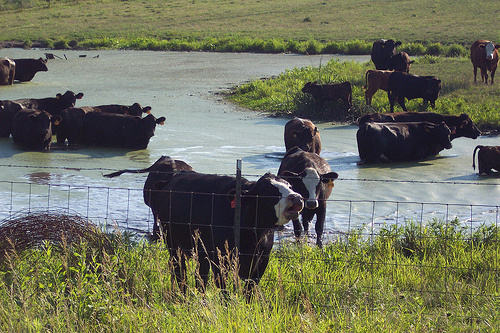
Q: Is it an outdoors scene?
A: Yes, it is outdoors.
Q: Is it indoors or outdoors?
A: It is outdoors.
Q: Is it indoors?
A: No, it is outdoors.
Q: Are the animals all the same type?
A: Yes, all the animals are cows.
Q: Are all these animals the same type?
A: Yes, all the animals are cows.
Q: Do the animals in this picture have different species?
A: No, all the animals are cows.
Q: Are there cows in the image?
A: Yes, there is a cow.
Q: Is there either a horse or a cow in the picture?
A: Yes, there is a cow.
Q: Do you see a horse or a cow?
A: Yes, there is a cow.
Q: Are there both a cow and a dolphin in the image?
A: No, there is a cow but no dolphins.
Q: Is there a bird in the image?
A: No, there are no birds.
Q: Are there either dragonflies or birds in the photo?
A: No, there are no birds or dragonflies.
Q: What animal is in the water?
A: The cow is in the water.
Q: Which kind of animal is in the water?
A: The animal is a cow.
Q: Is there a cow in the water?
A: Yes, there is a cow in the water.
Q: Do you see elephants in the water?
A: No, there is a cow in the water.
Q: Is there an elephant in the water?
A: No, there is a cow in the water.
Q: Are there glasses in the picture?
A: No, there are no glasses.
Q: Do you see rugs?
A: No, there are no rugs.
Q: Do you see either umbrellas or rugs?
A: No, there are no rugs or umbrellas.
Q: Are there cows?
A: Yes, there is a cow.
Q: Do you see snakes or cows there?
A: Yes, there is a cow.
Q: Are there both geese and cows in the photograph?
A: No, there is a cow but no geese.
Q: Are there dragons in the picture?
A: No, there are no dragons.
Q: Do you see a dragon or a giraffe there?
A: No, there are no dragons or giraffes.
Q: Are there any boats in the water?
A: No, there is a cow in the water.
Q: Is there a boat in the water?
A: No, there is a cow in the water.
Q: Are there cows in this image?
A: Yes, there is a cow.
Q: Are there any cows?
A: Yes, there is a cow.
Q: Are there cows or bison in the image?
A: Yes, there is a cow.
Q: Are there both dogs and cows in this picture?
A: No, there is a cow but no dogs.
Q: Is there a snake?
A: No, there are no snakes.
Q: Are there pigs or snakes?
A: No, there are no snakes or pigs.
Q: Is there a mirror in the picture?
A: No, there are no mirrors.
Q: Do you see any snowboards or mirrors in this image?
A: No, there are no mirrors or snowboards.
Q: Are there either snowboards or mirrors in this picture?
A: No, there are no mirrors or snowboards.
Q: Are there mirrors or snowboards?
A: No, there are no mirrors or snowboards.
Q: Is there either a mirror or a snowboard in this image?
A: No, there are no mirrors or snowboards.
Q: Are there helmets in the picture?
A: No, there are no helmets.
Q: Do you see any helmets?
A: No, there are no helmets.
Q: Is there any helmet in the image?
A: No, there are no helmets.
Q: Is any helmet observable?
A: No, there are no helmets.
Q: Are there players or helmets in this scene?
A: No, there are no helmets or players.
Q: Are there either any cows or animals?
A: Yes, there is a cow.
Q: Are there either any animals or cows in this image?
A: Yes, there is a cow.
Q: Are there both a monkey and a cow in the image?
A: No, there is a cow but no monkeys.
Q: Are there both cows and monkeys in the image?
A: No, there is a cow but no monkeys.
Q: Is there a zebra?
A: No, there are no zebras.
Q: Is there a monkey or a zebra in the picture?
A: No, there are no zebras or monkeys.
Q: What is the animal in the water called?
A: The animal is a cow.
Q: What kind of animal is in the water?
A: The animal is a cow.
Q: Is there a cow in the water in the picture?
A: Yes, there is a cow in the water.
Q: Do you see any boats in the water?
A: No, there is a cow in the water.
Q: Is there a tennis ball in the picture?
A: No, there are no tennis balls.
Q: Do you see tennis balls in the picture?
A: No, there are no tennis balls.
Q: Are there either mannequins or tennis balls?
A: No, there are no tennis balls or mannequins.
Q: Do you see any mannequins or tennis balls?
A: No, there are no tennis balls or mannequins.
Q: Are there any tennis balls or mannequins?
A: No, there are no tennis balls or mannequins.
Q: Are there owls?
A: No, there are no owls.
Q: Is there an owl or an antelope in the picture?
A: No, there are no owls or antelopes.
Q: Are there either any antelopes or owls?
A: No, there are no owls or antelopes.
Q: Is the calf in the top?
A: Yes, the calf is in the top of the image.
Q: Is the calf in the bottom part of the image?
A: No, the calf is in the top of the image.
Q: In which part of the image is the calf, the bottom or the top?
A: The calf is in the top of the image.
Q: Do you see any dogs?
A: No, there are no dogs.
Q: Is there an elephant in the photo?
A: No, there are no elephants.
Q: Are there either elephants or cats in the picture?
A: No, there are no elephants or cats.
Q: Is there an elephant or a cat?
A: No, there are no elephants or cats.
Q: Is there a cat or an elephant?
A: No, there are no elephants or cats.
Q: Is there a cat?
A: No, there are no cats.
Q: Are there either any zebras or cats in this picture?
A: No, there are no cats or zebras.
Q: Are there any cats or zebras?
A: No, there are no cats or zebras.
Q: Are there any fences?
A: Yes, there is a fence.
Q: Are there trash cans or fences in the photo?
A: Yes, there is a fence.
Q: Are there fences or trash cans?
A: Yes, there is a fence.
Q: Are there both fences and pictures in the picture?
A: No, there is a fence but no pictures.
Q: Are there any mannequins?
A: No, there are no mannequins.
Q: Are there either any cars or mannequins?
A: No, there are no mannequins or cars.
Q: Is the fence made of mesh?
A: Yes, the fence is made of mesh.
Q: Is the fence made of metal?
A: No, the fence is made of mesh.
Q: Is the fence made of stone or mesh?
A: The fence is made of mesh.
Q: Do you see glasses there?
A: No, there are no glasses.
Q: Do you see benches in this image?
A: No, there are no benches.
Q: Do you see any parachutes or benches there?
A: No, there are no benches or parachutes.